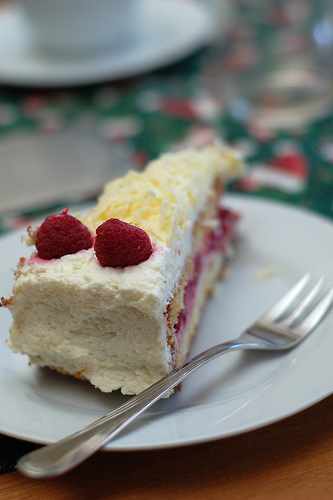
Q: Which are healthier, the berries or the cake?
A: The berries are healthier than the cake.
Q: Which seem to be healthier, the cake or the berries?
A: The berries are healthier than the cake.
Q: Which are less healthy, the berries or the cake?
A: The cake are less healthy than the berries.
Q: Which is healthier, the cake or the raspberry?
A: The raspberry is healthier than the cake.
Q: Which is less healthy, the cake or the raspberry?
A: The cake is less healthy than the raspberry.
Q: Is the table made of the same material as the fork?
A: No, the table is made of wood and the fork is made of metal.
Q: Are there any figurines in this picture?
A: No, there are no figurines.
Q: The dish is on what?
A: The dish is on the table.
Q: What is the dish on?
A: The dish is on the table.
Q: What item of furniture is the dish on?
A: The dish is on the table.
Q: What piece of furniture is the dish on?
A: The dish is on the table.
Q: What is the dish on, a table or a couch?
A: The dish is on a table.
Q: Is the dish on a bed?
A: No, the dish is on a table.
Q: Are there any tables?
A: Yes, there is a table.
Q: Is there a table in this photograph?
A: Yes, there is a table.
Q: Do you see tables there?
A: Yes, there is a table.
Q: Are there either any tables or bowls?
A: Yes, there is a table.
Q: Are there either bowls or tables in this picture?
A: Yes, there is a table.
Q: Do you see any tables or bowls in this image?
A: Yes, there is a table.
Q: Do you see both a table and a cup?
A: Yes, there are both a table and a cup.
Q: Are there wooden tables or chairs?
A: Yes, there is a wood table.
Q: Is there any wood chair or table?
A: Yes, there is a wood table.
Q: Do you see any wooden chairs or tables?
A: Yes, there is a wood table.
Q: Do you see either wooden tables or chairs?
A: Yes, there is a wood table.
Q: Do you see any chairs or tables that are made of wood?
A: Yes, the table is made of wood.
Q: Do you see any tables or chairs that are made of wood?
A: Yes, the table is made of wood.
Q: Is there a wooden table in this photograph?
A: Yes, there is a wood table.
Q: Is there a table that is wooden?
A: Yes, there is a table that is wooden.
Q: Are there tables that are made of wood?
A: Yes, there is a table that is made of wood.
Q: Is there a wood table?
A: Yes, there is a table that is made of wood.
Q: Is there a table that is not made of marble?
A: Yes, there is a table that is made of wood.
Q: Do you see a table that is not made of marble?
A: Yes, there is a table that is made of wood.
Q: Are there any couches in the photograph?
A: No, there are no couches.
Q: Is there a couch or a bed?
A: No, there are no couches or beds.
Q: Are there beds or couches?
A: No, there are no couches or beds.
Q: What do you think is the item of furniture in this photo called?
A: The piece of furniture is a table.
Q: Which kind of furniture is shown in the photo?
A: The furniture is a table.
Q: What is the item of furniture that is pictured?
A: The piece of furniture is a table.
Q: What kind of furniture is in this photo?
A: The furniture is a table.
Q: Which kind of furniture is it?
A: The piece of furniture is a table.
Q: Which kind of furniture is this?
A: This is a table.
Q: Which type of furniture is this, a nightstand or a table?
A: This is a table.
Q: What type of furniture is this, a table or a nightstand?
A: This is a table.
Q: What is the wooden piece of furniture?
A: The piece of furniture is a table.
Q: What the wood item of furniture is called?
A: The piece of furniture is a table.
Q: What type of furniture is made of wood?
A: The furniture is a table.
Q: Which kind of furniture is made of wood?
A: The furniture is a table.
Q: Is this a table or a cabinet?
A: This is a table.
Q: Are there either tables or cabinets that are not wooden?
A: No, there is a table but it is wooden.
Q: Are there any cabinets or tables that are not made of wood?
A: No, there is a table but it is made of wood.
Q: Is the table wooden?
A: Yes, the table is wooden.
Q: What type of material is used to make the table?
A: The table is made of wood.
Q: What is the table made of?
A: The table is made of wood.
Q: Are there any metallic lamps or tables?
A: No, there is a table but it is wooden.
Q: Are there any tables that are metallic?
A: No, there is a table but it is wooden.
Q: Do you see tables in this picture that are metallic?
A: No, there is a table but it is wooden.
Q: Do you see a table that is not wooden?
A: No, there is a table but it is wooden.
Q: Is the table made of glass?
A: No, the table is made of wood.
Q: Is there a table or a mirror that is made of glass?
A: No, there is a table but it is made of wood.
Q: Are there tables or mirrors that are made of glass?
A: No, there is a table but it is made of wood.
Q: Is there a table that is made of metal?
A: No, there is a table but it is made of wood.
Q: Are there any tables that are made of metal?
A: No, there is a table but it is made of wood.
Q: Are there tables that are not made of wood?
A: No, there is a table but it is made of wood.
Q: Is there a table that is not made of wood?
A: No, there is a table but it is made of wood.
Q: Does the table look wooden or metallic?
A: The table is wooden.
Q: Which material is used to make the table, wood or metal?
A: The table is made of wood.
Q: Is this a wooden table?
A: Yes, this is a wooden table.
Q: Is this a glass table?
A: No, this is a wooden table.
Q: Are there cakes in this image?
A: Yes, there is a cake.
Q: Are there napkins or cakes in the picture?
A: Yes, there is a cake.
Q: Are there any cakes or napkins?
A: Yes, there is a cake.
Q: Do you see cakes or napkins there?
A: Yes, there is a cake.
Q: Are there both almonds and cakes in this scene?
A: No, there is a cake but no almonds.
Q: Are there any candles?
A: No, there are no candles.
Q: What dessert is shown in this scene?
A: The dessert is a cake.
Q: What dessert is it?
A: The dessert is a cake.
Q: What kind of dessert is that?
A: This is a cake.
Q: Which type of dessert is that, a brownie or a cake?
A: This is a cake.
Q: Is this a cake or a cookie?
A: This is a cake.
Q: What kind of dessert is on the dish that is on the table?
A: The dessert is a cake.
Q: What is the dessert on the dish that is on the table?
A: The dessert is a cake.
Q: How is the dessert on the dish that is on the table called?
A: The dessert is a cake.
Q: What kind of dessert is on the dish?
A: The dessert is a cake.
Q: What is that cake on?
A: The cake is on the dish.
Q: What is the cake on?
A: The cake is on the dish.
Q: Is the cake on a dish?
A: Yes, the cake is on a dish.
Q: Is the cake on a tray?
A: No, the cake is on a dish.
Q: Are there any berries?
A: Yes, there are berries.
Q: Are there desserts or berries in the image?
A: Yes, there are berries.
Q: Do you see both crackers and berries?
A: No, there are berries but no crackers.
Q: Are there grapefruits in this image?
A: No, there are no grapefruits.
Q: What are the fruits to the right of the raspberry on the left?
A: The fruits are berries.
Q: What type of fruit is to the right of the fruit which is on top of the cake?
A: The fruits are berries.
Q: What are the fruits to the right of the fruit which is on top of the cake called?
A: The fruits are berries.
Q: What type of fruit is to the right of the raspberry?
A: The fruits are berries.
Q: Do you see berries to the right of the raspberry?
A: Yes, there are berries to the right of the raspberry.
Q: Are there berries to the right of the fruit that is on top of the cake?
A: Yes, there are berries to the right of the raspberry.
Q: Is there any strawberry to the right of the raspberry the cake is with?
A: No, there are berries to the right of the raspberry.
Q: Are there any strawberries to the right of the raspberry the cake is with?
A: No, there are berries to the right of the raspberry.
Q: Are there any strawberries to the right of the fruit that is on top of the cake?
A: No, there are berries to the right of the raspberry.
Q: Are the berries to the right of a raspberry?
A: Yes, the berries are to the right of a raspberry.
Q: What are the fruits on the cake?
A: The fruits are berries.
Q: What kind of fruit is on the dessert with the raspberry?
A: The fruits are berries.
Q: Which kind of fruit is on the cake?
A: The fruits are berries.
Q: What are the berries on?
A: The berries are on the cake.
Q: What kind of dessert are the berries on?
A: The berries are on the cake.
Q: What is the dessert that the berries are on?
A: The dessert is a cake.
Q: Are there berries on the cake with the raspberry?
A: Yes, there are berries on the cake.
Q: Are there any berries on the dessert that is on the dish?
A: Yes, there are berries on the cake.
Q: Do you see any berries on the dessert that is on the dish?
A: Yes, there are berries on the cake.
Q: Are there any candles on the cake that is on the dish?
A: No, there are berries on the cake.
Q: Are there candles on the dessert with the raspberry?
A: No, there are berries on the cake.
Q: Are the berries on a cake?
A: Yes, the berries are on a cake.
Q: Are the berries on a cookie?
A: No, the berries are on a cake.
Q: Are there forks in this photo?
A: Yes, there is a fork.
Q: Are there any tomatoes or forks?
A: Yes, there is a fork.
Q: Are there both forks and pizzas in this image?
A: No, there is a fork but no pizzas.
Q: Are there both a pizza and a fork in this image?
A: No, there is a fork but no pizzas.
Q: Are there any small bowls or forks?
A: Yes, there is a small fork.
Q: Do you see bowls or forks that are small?
A: Yes, the fork is small.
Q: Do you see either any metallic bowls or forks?
A: Yes, there is a metal fork.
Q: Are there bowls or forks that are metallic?
A: Yes, the fork is metallic.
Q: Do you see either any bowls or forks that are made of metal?
A: Yes, the fork is made of metal.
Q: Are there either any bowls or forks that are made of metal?
A: Yes, the fork is made of metal.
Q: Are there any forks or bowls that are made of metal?
A: Yes, the fork is made of metal.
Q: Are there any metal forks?
A: Yes, there is a metal fork.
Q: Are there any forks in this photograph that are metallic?
A: Yes, there is a fork that is metallic.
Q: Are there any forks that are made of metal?
A: Yes, there is a fork that is made of metal.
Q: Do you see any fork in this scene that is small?
A: Yes, there is a small fork.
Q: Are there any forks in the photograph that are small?
A: Yes, there is a fork that is small.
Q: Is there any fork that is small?
A: Yes, there is a fork that is small.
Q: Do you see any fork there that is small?
A: Yes, there is a fork that is small.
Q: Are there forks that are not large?
A: Yes, there is a small fork.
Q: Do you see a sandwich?
A: No, there are no sandwiches.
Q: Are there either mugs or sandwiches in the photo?
A: No, there are no sandwiches or mugs.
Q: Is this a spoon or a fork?
A: This is a fork.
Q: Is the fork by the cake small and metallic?
A: Yes, the fork is small and metallic.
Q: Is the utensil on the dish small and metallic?
A: Yes, the fork is small and metallic.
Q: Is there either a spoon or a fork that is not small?
A: No, there is a fork but it is small.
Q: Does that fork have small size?
A: Yes, the fork is small.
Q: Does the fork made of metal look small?
A: Yes, the fork is small.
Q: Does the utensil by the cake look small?
A: Yes, the fork is small.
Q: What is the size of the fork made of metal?
A: The fork is small.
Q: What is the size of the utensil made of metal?
A: The fork is small.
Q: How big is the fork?
A: The fork is small.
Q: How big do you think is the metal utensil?
A: The fork is small.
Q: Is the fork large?
A: No, the fork is small.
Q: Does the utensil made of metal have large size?
A: No, the fork is small.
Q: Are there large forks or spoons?
A: No, there is a fork but it is small.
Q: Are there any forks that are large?
A: No, there is a fork but it is small.